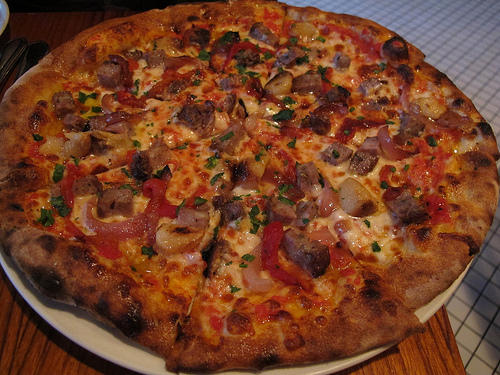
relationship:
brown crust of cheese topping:
[5, 239, 163, 353] [0, 0, 500, 374]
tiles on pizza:
[448, 313, 498, 344] [456, 5, 463, 328]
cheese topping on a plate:
[0, 0, 500, 374] [407, 256, 476, 323]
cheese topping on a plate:
[0, 0, 500, 374] [2, 245, 412, 373]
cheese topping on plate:
[0, 0, 500, 374] [0, 53, 474, 375]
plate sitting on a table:
[0, 53, 474, 375] [337, 303, 469, 374]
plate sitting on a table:
[0, 53, 474, 375] [2, 263, 157, 373]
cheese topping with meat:
[0, 0, 500, 374] [260, 71, 292, 100]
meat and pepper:
[260, 71, 292, 100] [261, 221, 298, 285]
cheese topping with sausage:
[0, 0, 500, 374] [278, 224, 331, 274]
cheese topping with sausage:
[0, 0, 500, 374] [387, 190, 427, 221]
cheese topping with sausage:
[0, 0, 500, 374] [209, 175, 231, 207]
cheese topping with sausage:
[0, 0, 500, 374] [131, 147, 154, 182]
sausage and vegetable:
[278, 224, 331, 274] [99, 189, 135, 221]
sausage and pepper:
[387, 190, 427, 221] [261, 221, 298, 285]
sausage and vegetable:
[209, 175, 231, 207] [427, 134, 434, 146]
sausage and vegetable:
[131, 147, 154, 182] [47, 196, 72, 216]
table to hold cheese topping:
[4, 6, 468, 373] [0, 0, 500, 374]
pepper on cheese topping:
[257, 218, 317, 293] [0, 0, 500, 374]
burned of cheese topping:
[10, 227, 159, 346] [0, 0, 500, 374]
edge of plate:
[2, 44, 478, 374] [2, 56, 482, 374]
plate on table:
[0, 258, 475, 373] [4, 6, 468, 373]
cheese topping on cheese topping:
[12, 33, 457, 328] [0, 0, 500, 374]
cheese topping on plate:
[0, 0, 500, 374] [54, 286, 499, 357]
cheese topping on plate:
[0, 0, 500, 374] [21, 31, 481, 367]